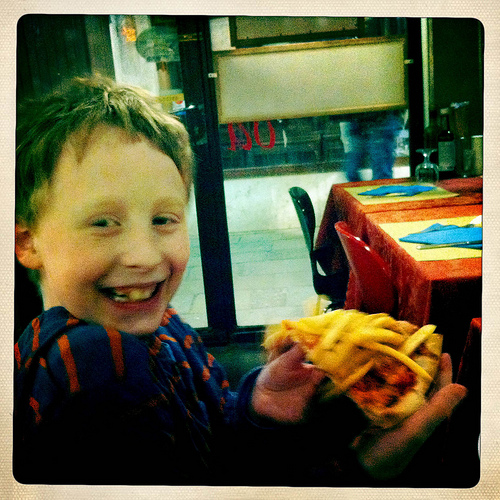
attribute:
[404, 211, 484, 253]
napkin — blue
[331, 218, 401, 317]
chair — dark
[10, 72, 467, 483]
he — a slice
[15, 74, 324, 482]
boy — little, grinning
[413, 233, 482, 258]
knife — silver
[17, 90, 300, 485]
boy — smiling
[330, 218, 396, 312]
chair — red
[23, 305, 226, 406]
hoodie — blue, red stripes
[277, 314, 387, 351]
fry — french fry, golden colored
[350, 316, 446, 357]
french fry — golden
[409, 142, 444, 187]
glass — wine glass, upside down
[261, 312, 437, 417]
pizza — slice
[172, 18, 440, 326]
window — large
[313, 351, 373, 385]
french fry — golden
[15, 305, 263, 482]
sweater — orange, black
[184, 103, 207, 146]
handle — metal, door handle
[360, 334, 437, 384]
french fry — golden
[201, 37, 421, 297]
window — glass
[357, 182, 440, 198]
napkin — blue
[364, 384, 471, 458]
finger — small, white, child's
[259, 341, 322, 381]
finger — small, white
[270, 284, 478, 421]
pizza — slice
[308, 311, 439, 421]
slice — pizza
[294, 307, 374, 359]
french fry — golden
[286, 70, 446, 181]
people — a pair